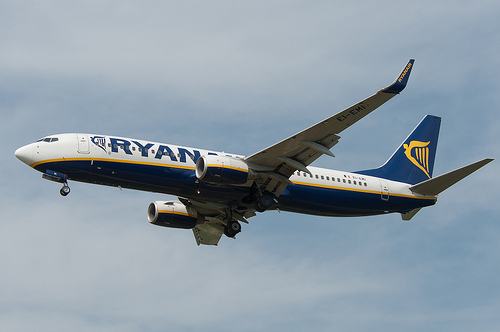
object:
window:
[309, 173, 314, 179]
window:
[302, 172, 307, 178]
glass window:
[346, 179, 353, 185]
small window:
[315, 174, 321, 180]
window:
[296, 171, 301, 177]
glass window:
[302, 171, 308, 178]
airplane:
[10, 57, 499, 249]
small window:
[324, 174, 331, 182]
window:
[107, 142, 114, 148]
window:
[336, 177, 341, 184]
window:
[130, 145, 137, 152]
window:
[363, 182, 368, 187]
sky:
[0, 2, 500, 332]